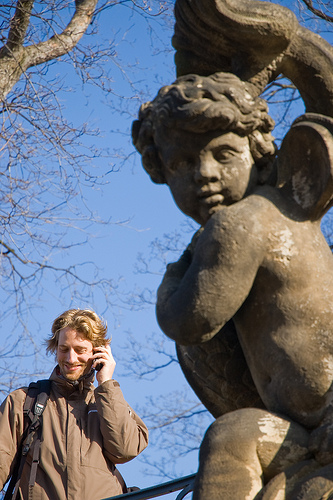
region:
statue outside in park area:
[110, 1, 332, 496]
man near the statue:
[2, 299, 151, 499]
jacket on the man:
[2, 371, 131, 497]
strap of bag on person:
[23, 379, 44, 499]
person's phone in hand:
[82, 344, 103, 382]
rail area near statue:
[105, 467, 202, 499]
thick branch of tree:
[0, 2, 124, 101]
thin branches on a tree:
[12, 100, 86, 219]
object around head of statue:
[164, 2, 332, 218]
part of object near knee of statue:
[172, 337, 255, 412]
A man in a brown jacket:
[0, 304, 149, 499]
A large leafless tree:
[0, 0, 183, 395]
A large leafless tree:
[110, 1, 331, 479]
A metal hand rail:
[98, 471, 195, 499]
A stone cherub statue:
[122, 1, 330, 499]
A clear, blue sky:
[0, 1, 332, 498]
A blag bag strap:
[4, 376, 49, 499]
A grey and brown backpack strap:
[21, 381, 43, 492]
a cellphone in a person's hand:
[89, 343, 102, 369]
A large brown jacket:
[0, 365, 150, 499]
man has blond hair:
[52, 308, 108, 360]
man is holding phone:
[55, 317, 133, 397]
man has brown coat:
[10, 365, 127, 485]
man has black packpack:
[3, 373, 69, 476]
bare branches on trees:
[12, 91, 156, 389]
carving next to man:
[141, 14, 306, 499]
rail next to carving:
[158, 461, 203, 496]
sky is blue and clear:
[57, 103, 172, 280]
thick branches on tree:
[0, 15, 93, 83]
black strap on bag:
[20, 382, 45, 475]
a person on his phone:
[4, 304, 149, 498]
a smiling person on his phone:
[6, 298, 152, 498]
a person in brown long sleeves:
[0, 306, 151, 499]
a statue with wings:
[118, 77, 331, 495]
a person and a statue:
[6, 8, 320, 498]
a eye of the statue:
[214, 147, 238, 163]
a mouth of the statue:
[191, 184, 225, 206]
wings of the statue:
[270, 104, 331, 222]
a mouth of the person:
[61, 363, 83, 372]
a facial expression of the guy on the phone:
[44, 305, 116, 390]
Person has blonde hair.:
[64, 306, 103, 345]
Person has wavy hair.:
[62, 310, 95, 335]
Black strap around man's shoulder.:
[22, 375, 65, 460]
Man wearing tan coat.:
[52, 406, 96, 467]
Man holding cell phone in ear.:
[78, 342, 124, 381]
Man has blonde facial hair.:
[56, 360, 103, 380]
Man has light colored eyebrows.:
[42, 338, 100, 356]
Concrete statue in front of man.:
[162, 299, 276, 437]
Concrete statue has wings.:
[269, 119, 317, 221]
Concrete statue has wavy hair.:
[141, 82, 273, 161]